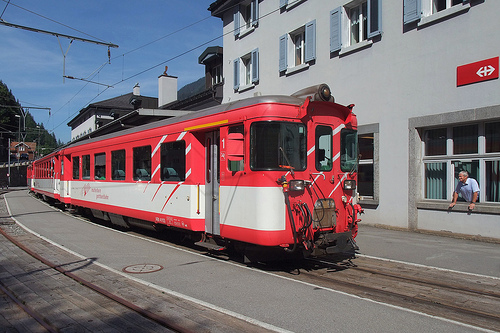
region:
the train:
[164, 15, 298, 267]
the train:
[221, 125, 295, 277]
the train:
[196, 127, 273, 299]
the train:
[232, 187, 312, 319]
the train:
[213, 124, 333, 331]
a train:
[177, 94, 300, 297]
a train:
[216, 102, 335, 312]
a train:
[215, 182, 300, 258]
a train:
[145, 17, 312, 252]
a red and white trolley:
[78, 85, 351, 264]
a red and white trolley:
[26, 144, 67, 198]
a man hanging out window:
[444, 169, 484, 213]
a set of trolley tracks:
[297, 247, 497, 322]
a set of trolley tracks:
[0, 226, 179, 327]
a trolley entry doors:
[199, 133, 222, 234]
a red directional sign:
[447, 62, 498, 84]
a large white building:
[219, 2, 494, 237]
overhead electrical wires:
[2, 0, 295, 162]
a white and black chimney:
[150, 66, 177, 106]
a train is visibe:
[175, 150, 352, 330]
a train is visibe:
[239, 105, 339, 322]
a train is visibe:
[203, 155, 277, 263]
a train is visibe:
[185, 188, 298, 273]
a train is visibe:
[130, 0, 270, 270]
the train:
[162, 95, 262, 252]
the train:
[234, 161, 282, 222]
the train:
[177, 144, 254, 324]